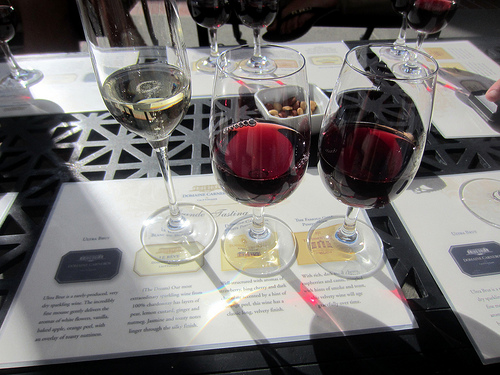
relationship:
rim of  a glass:
[139, 199, 388, 290] [127, 122, 409, 289]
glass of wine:
[127, 122, 409, 289] [222, 123, 415, 200]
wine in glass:
[222, 123, 415, 200] [127, 122, 409, 289]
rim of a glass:
[139, 199, 388, 290] [127, 122, 409, 289]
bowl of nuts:
[252, 83, 329, 124] [267, 93, 321, 113]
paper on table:
[0, 151, 417, 343] [5, 35, 499, 374]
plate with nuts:
[252, 83, 329, 124] [269, 94, 324, 117]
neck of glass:
[151, 142, 196, 233] [127, 122, 409, 289]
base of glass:
[220, 214, 298, 275] [77, 1, 220, 264]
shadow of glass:
[248, 248, 415, 371] [77, 1, 220, 264]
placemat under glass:
[2, 158, 422, 373] [305, 43, 440, 280]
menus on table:
[9, 54, 494, 357] [5, 35, 499, 374]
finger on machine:
[484, 80, 498, 112] [468, 86, 498, 132]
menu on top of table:
[4, 170, 424, 370] [5, 35, 499, 374]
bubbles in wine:
[218, 111, 258, 134] [213, 120, 308, 203]